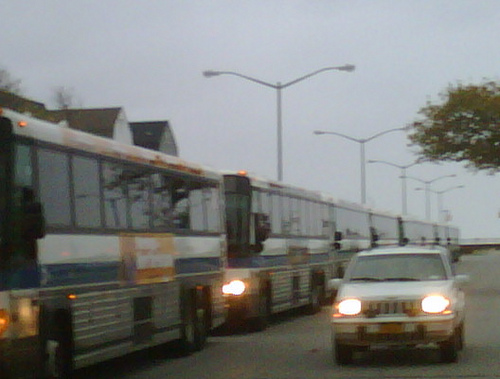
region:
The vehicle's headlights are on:
[318, 285, 465, 335]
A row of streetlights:
[203, 60, 466, 216]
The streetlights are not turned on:
[199, 55, 461, 217]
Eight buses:
[23, 138, 494, 337]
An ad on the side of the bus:
[108, 223, 198, 286]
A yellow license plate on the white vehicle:
[369, 318, 418, 339]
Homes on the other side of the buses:
[16, 78, 196, 154]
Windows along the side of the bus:
[24, 150, 224, 227]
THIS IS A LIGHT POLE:
[200, 62, 365, 182]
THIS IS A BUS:
[1, 108, 227, 373]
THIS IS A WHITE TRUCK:
[325, 245, 468, 362]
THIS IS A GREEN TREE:
[404, 74, 497, 183]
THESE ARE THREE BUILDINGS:
[2, 89, 179, 159]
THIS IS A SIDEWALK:
[128, 251, 498, 376]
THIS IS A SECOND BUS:
[225, 171, 332, 334]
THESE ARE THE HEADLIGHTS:
[335, 294, 452, 316]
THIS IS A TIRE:
[180, 290, 210, 353]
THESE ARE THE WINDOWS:
[10, 137, 227, 240]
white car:
[326, 233, 401, 328]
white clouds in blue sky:
[75, 21, 130, 58]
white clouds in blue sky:
[205, 107, 222, 128]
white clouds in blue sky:
[395, 5, 456, 62]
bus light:
[215, 272, 245, 297]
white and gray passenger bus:
[15, 108, 235, 355]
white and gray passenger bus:
[238, 172, 340, 317]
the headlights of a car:
[322, 271, 495, 333]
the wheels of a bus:
[162, 284, 251, 355]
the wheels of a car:
[321, 325, 383, 365]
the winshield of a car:
[331, 242, 458, 291]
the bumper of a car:
[326, 301, 484, 344]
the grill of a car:
[333, 289, 425, 322]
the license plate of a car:
[360, 305, 405, 347]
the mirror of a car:
[320, 267, 347, 288]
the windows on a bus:
[39, 135, 261, 238]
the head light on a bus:
[215, 250, 268, 322]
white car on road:
[349, 243, 465, 352]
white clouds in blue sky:
[22, 13, 116, 70]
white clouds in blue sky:
[132, 25, 167, 48]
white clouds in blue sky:
[184, 94, 231, 129]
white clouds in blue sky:
[363, 32, 409, 57]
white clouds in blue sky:
[396, 20, 426, 50]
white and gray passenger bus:
[3, 120, 223, 360]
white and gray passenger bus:
[237, 170, 327, 305]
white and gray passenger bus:
[330, 192, 370, 248]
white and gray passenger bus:
[364, 199, 401, 236]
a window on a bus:
[68, 150, 105, 230]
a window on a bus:
[102, 155, 130, 228]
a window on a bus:
[129, 162, 151, 224]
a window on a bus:
[150, 165, 173, 225]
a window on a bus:
[165, 163, 197, 235]